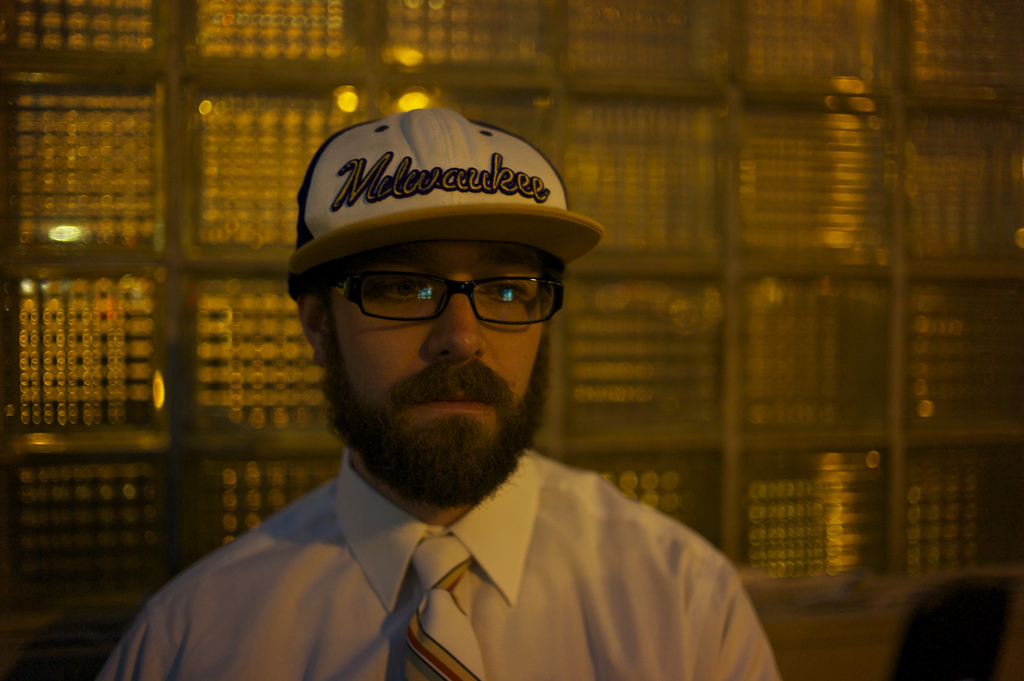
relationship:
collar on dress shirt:
[316, 446, 585, 601] [94, 480, 788, 675]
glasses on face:
[318, 257, 576, 330] [319, 227, 568, 485]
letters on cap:
[336, 161, 553, 205] [325, 153, 566, 217]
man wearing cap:
[103, 45, 710, 676] [276, 106, 608, 269]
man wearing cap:
[102, 106, 776, 679] [288, 113, 615, 282]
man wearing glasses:
[102, 106, 776, 679] [334, 266, 579, 318]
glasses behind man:
[318, 272, 565, 323] [93, 89, 791, 671]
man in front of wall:
[102, 106, 776, 679] [4, 5, 974, 677]